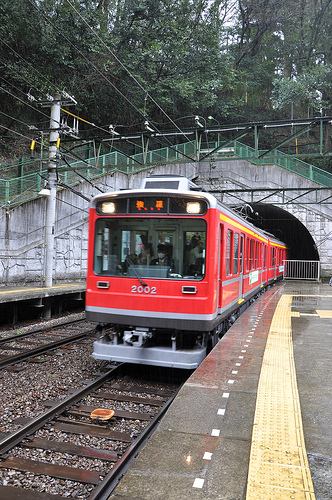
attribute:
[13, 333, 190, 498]
track — here, marked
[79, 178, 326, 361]
train — here, red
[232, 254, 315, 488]
line — yellow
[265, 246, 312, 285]
fence — metal, here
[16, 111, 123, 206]
stiar case — here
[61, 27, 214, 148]
wire — electrical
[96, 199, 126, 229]
light — small, hanging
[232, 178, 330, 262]
tunnel — black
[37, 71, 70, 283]
pole — white, here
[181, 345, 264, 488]
lines — here, white, dotted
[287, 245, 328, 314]
gate — metal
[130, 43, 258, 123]
tree — tall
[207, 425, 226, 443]
square — white